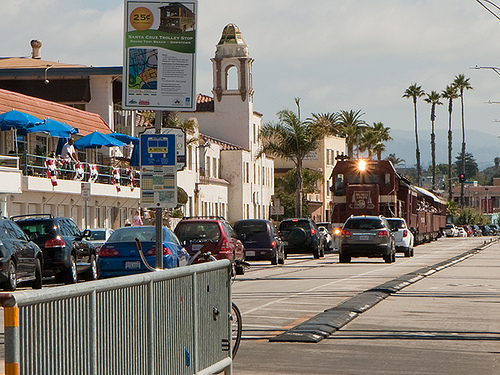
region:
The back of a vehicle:
[331, 205, 396, 265]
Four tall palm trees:
[395, 65, 475, 205]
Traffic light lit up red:
[450, 162, 472, 192]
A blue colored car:
[86, 215, 196, 281]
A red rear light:
[35, 225, 70, 255]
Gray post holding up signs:
[145, 196, 170, 271]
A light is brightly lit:
[345, 147, 380, 182]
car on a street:
[340, 208, 391, 266]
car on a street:
[288, 210, 314, 250]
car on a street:
[248, 211, 274, 263]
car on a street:
[195, 211, 236, 246]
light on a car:
[372, 225, 389, 240]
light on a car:
[340, 225, 356, 238]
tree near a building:
[398, 77, 423, 114]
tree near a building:
[427, 86, 447, 119]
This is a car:
[329, 204, 396, 266]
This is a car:
[382, 206, 429, 268]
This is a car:
[272, 202, 326, 262]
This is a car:
[231, 203, 291, 273]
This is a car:
[174, 197, 252, 289]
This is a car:
[101, 215, 188, 296]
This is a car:
[15, 190, 101, 285]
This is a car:
[80, 215, 122, 270]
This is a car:
[316, 212, 338, 250]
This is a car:
[3, 211, 56, 315]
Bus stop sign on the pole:
[119, 110, 188, 285]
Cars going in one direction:
[2, 201, 498, 281]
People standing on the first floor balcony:
[6, 93, 186, 195]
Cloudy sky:
[1, 3, 498, 194]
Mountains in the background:
[307, 96, 497, 176]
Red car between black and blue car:
[92, 211, 296, 276]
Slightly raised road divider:
[269, 239, 496, 351]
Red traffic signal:
[453, 164, 471, 188]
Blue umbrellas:
[1, 109, 139, 176]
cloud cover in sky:
[2, 0, 497, 132]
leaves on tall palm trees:
[404, 74, 472, 202]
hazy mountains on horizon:
[377, 126, 498, 167]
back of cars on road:
[0, 209, 414, 296]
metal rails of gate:
[7, 260, 234, 373]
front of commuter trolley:
[328, 158, 441, 246]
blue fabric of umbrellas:
[0, 105, 132, 165]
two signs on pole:
[121, 0, 196, 267]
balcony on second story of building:
[1, 93, 151, 233]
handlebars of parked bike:
[132, 237, 213, 270]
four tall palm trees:
[405, 70, 476, 191]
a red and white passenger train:
[334, 158, 459, 237]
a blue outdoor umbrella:
[6, 105, 41, 130]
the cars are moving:
[67, 184, 397, 309]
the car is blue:
[104, 223, 200, 265]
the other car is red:
[179, 198, 273, 295]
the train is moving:
[304, 143, 455, 249]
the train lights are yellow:
[314, 123, 414, 203]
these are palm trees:
[384, 68, 483, 149]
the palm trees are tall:
[382, 38, 481, 122]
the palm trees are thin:
[410, 88, 482, 183]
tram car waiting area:
[6, 219, 247, 373]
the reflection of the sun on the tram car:
[332, 138, 388, 193]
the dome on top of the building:
[210, 25, 260, 115]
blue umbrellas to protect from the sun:
[2, 97, 129, 157]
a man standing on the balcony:
[25, 131, 136, 196]